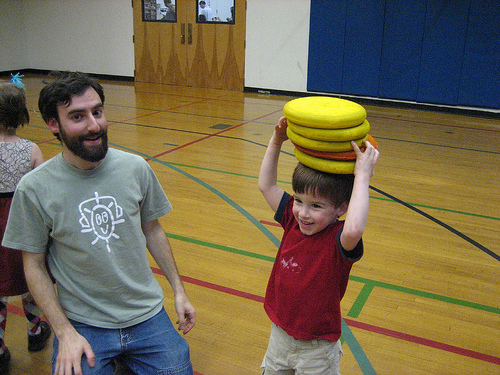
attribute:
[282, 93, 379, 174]
frisbees — yellow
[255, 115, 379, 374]
boy — little, smiling, standing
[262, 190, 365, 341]
shirt — red, gray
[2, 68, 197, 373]
man — happy, smiling, kneeling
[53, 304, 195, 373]
jeans — blue, denim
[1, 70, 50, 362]
girl — little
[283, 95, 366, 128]
frisbee — yellow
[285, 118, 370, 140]
frisbee — yellow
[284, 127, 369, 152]
frisbee — yellow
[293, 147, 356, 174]
frisbee — yellow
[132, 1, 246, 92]
doors — double, wooden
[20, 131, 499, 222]
line — green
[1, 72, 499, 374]
floor — wood, multicolored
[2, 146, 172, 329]
shirt — green, grey, white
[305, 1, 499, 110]
padding — blue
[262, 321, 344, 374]
pants — white, khaki, light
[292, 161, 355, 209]
hair — short, brown, dark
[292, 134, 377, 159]
frisbee — orange, bright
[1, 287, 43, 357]
tights — argyle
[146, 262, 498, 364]
line — red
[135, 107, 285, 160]
line — red